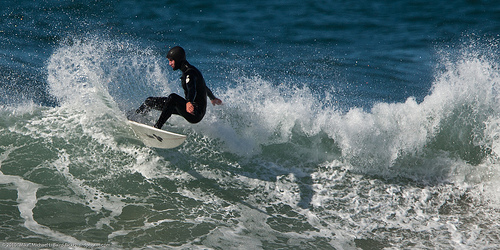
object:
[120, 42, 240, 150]
person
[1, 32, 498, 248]
wave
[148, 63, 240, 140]
wet suit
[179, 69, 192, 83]
costume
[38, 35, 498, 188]
white foam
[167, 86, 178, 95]
knee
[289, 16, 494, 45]
ripple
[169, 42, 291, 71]
ripple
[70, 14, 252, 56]
ripple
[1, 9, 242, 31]
ripple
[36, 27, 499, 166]
splash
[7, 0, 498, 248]
water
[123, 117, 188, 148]
white surfboard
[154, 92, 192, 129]
leg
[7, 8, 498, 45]
blue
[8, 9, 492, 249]
ocean